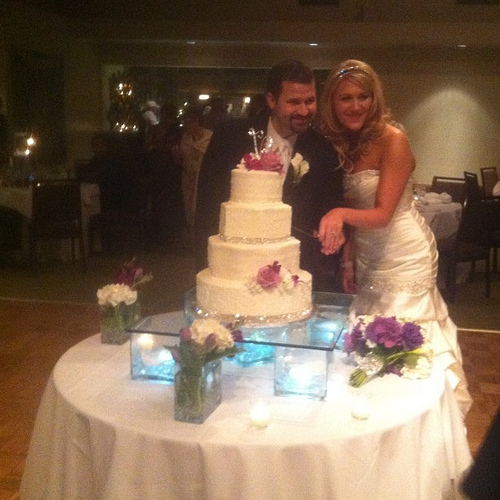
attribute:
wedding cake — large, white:
[187, 126, 316, 331]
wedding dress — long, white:
[346, 174, 470, 409]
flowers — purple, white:
[334, 306, 431, 374]